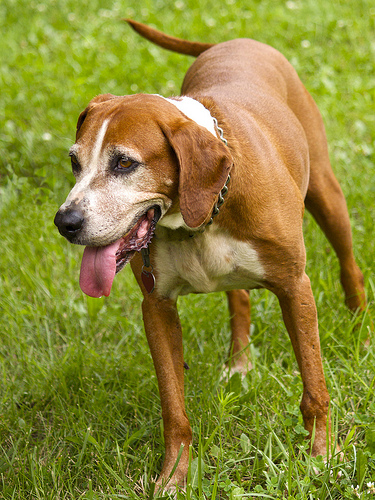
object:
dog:
[48, 38, 367, 497]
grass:
[4, 8, 27, 39]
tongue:
[77, 247, 119, 300]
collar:
[167, 97, 229, 239]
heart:
[139, 269, 160, 295]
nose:
[53, 208, 84, 240]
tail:
[119, 14, 214, 62]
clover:
[217, 477, 235, 499]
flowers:
[368, 480, 374, 499]